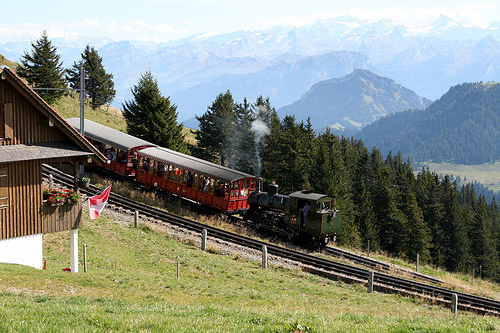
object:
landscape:
[2, 3, 498, 332]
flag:
[88, 183, 113, 220]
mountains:
[0, 0, 499, 70]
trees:
[16, 28, 500, 286]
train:
[57, 117, 261, 214]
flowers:
[38, 188, 81, 205]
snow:
[13, 12, 500, 48]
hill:
[0, 49, 499, 333]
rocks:
[44, 179, 306, 270]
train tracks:
[42, 162, 499, 315]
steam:
[225, 105, 272, 178]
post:
[70, 229, 79, 273]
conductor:
[299, 203, 311, 226]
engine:
[244, 181, 342, 247]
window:
[40, 160, 78, 203]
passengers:
[106, 138, 255, 199]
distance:
[0, 0, 499, 169]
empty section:
[326, 240, 500, 317]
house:
[0, 65, 110, 273]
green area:
[0, 177, 500, 332]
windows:
[101, 144, 261, 199]